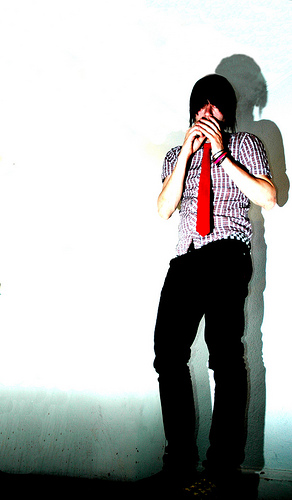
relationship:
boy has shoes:
[138, 71, 277, 499] [133, 473, 238, 498]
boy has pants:
[138, 71, 277, 499] [153, 239, 256, 466]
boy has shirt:
[138, 71, 277, 499] [162, 132, 273, 257]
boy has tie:
[138, 71, 277, 499] [196, 142, 213, 237]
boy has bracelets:
[138, 71, 277, 499] [207, 147, 228, 168]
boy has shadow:
[138, 71, 277, 499] [188, 53, 290, 500]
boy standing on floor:
[138, 71, 277, 499] [1, 473, 134, 500]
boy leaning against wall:
[138, 71, 277, 499] [2, 1, 291, 498]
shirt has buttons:
[162, 132, 273, 257] [190, 162, 202, 235]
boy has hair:
[138, 71, 277, 499] [189, 76, 238, 133]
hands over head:
[183, 117, 225, 153] [187, 75, 237, 133]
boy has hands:
[138, 71, 277, 499] [183, 117, 225, 153]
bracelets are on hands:
[207, 147, 228, 168] [183, 117, 225, 153]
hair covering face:
[189, 76, 238, 133] [196, 101, 225, 127]